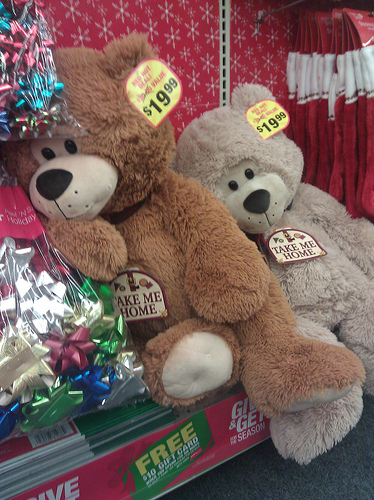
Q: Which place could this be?
A: It is a store.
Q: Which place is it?
A: It is a store.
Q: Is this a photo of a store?
A: Yes, it is showing a store.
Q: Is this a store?
A: Yes, it is a store.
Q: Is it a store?
A: Yes, it is a store.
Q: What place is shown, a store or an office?
A: It is a store.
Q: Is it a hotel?
A: No, it is a store.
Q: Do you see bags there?
A: Yes, there is a bag.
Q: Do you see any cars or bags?
A: Yes, there is a bag.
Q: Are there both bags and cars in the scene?
A: No, there is a bag but no cars.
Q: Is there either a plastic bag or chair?
A: Yes, there is a plastic bag.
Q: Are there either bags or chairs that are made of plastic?
A: Yes, the bag is made of plastic.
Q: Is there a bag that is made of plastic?
A: Yes, there is a bag that is made of plastic.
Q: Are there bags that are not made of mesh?
A: Yes, there is a bag that is made of plastic.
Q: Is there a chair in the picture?
A: No, there are no chairs.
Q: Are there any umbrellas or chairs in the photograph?
A: No, there are no chairs or umbrellas.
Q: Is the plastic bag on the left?
A: Yes, the bag is on the left of the image.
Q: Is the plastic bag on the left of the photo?
A: Yes, the bag is on the left of the image.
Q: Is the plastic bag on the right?
A: No, the bag is on the left of the image.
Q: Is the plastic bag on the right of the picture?
A: No, the bag is on the left of the image.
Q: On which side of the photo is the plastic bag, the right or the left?
A: The bag is on the left of the image.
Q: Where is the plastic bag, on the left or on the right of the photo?
A: The bag is on the left of the image.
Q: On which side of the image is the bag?
A: The bag is on the left of the image.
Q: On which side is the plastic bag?
A: The bag is on the left of the image.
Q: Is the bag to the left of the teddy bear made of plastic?
A: Yes, the bag is made of plastic.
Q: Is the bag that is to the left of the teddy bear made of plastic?
A: Yes, the bag is made of plastic.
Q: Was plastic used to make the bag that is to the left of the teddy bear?
A: Yes, the bag is made of plastic.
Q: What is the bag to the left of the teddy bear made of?
A: The bag is made of plastic.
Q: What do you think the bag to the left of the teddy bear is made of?
A: The bag is made of plastic.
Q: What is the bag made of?
A: The bag is made of plastic.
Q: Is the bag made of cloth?
A: No, the bag is made of plastic.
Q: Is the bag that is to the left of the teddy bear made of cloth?
A: No, the bag is made of plastic.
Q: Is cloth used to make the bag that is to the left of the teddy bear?
A: No, the bag is made of plastic.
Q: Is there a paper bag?
A: No, there is a bag but it is made of plastic.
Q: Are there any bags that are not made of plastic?
A: No, there is a bag but it is made of plastic.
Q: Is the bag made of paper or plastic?
A: The bag is made of plastic.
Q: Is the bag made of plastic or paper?
A: The bag is made of plastic.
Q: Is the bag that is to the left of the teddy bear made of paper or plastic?
A: The bag is made of plastic.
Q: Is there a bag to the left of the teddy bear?
A: Yes, there is a bag to the left of the teddy bear.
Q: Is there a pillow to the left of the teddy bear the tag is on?
A: No, there is a bag to the left of the teddy bear.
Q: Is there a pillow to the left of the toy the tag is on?
A: No, there is a bag to the left of the teddy bear.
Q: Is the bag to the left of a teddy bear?
A: Yes, the bag is to the left of a teddy bear.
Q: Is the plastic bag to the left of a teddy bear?
A: Yes, the bag is to the left of a teddy bear.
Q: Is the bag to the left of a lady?
A: No, the bag is to the left of a teddy bear.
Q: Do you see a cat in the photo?
A: No, there are no cats.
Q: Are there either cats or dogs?
A: No, there are no cats or dogs.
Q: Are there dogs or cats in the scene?
A: No, there are no cats or dogs.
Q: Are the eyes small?
A: Yes, the eyes are small.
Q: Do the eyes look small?
A: Yes, the eyes are small.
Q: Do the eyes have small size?
A: Yes, the eyes are small.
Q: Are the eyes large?
A: No, the eyes are small.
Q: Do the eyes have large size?
A: No, the eyes are small.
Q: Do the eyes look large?
A: No, the eyes are small.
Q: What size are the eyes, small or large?
A: The eyes are small.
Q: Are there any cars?
A: No, there are no cars.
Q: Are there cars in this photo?
A: No, there are no cars.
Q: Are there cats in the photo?
A: No, there are no cats.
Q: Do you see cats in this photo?
A: No, there are no cats.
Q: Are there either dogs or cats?
A: No, there are no cats or dogs.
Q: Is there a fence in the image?
A: No, there are no fences.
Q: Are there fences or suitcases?
A: No, there are no fences or suitcases.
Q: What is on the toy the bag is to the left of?
A: The tag is on the teddy bear.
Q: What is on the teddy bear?
A: The tag is on the teddy bear.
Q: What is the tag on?
A: The tag is on the teddy bear.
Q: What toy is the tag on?
A: The tag is on the teddy bear.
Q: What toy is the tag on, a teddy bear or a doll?
A: The tag is on a teddy bear.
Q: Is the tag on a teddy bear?
A: Yes, the tag is on a teddy bear.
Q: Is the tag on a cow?
A: No, the tag is on a teddy bear.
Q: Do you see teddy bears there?
A: Yes, there is a teddy bear.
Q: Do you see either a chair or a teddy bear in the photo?
A: Yes, there is a teddy bear.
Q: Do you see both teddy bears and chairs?
A: No, there is a teddy bear but no chairs.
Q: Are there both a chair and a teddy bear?
A: No, there is a teddy bear but no chairs.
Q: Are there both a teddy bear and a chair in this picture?
A: No, there is a teddy bear but no chairs.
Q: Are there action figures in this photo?
A: No, there are no action figures.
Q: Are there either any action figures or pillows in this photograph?
A: No, there are no action figures or pillows.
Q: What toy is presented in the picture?
A: The toy is a teddy bear.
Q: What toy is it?
A: The toy is a teddy bear.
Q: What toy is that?
A: This is a teddy bear.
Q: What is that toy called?
A: This is a teddy bear.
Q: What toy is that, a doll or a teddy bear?
A: This is a teddy bear.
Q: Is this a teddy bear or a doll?
A: This is a teddy bear.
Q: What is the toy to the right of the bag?
A: The toy is a teddy bear.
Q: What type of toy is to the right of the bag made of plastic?
A: The toy is a teddy bear.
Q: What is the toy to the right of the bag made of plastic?
A: The toy is a teddy bear.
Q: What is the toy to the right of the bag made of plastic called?
A: The toy is a teddy bear.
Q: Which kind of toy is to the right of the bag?
A: The toy is a teddy bear.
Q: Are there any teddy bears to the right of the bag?
A: Yes, there is a teddy bear to the right of the bag.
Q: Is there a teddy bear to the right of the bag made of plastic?
A: Yes, there is a teddy bear to the right of the bag.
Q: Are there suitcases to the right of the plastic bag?
A: No, there is a teddy bear to the right of the bag.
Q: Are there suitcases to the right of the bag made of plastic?
A: No, there is a teddy bear to the right of the bag.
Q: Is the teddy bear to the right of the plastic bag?
A: Yes, the teddy bear is to the right of the bag.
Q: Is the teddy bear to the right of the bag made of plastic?
A: Yes, the teddy bear is to the right of the bag.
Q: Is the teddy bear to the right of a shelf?
A: No, the teddy bear is to the right of the bag.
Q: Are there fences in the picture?
A: No, there are no fences.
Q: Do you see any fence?
A: No, there are no fences.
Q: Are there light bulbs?
A: No, there are no light bulbs.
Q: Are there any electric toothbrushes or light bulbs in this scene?
A: No, there are no light bulbs or electric toothbrushes.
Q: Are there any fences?
A: No, there are no fences.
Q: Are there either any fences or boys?
A: No, there are no fences or boys.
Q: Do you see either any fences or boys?
A: No, there are no fences or boys.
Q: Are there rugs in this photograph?
A: No, there are no rugs.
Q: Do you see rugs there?
A: No, there are no rugs.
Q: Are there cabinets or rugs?
A: No, there are no rugs or cabinets.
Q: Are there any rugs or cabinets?
A: No, there are no rugs or cabinets.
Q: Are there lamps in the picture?
A: No, there are no lamps.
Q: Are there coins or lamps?
A: No, there are no lamps or coins.